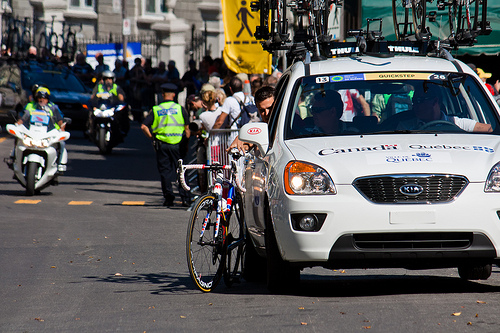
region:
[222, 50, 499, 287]
white car made by kia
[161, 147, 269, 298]
racing bicycle leaned against car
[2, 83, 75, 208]
man on a white motorcycle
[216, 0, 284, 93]
yellow sign with a black stick man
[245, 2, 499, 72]
bicycle rack on top of a white car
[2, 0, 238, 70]
grey stone building in the back ground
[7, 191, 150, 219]
yellow squares painted on the black road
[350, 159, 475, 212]
silver grill of the white car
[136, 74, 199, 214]
man wearing a yellow fluorescent vest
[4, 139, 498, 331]
black asphalt paved road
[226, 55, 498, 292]
a white car driving down a street.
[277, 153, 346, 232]
a right front headlight.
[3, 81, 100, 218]
a cop on a motorcycle.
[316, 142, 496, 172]
words painted on a hood.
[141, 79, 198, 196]
a neon green vest.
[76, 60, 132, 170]
a cop on a motorcycle.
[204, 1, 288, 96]
a banner with a man on it.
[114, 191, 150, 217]
the yellow stripe.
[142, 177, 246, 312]
the front tire of a bike.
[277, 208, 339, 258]
a right front light.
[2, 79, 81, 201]
a policeman riding a motorcycle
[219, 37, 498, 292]
car is white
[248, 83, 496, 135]
three persons in a car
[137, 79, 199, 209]
policeman with green vest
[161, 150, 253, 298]
bike lean on car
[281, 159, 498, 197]
headlights of car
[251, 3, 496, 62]
support to carry bikes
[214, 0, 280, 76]
yellow flag on a pole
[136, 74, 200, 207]
policeman wearing blue cap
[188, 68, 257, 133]
people behind a gate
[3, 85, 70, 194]
police officer riding a white and silver motorcycle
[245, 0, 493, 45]
the wheels of bicycles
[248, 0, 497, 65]
bicycles hitched to top of KIA white car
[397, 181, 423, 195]
the KIA logo on the front grill of white car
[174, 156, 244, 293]
white, blue and red bicycle against the white car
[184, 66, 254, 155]
a crowd of people behind the fence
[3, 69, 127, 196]
two motorcyclists driving motorcycles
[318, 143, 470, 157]
Canada Quebec written on hood of white car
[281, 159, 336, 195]
right head lights on the white car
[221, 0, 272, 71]
white sign with symbol of man walking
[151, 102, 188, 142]
the vest is green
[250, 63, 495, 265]
the make is kia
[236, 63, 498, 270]
the car is white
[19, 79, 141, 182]
the motorbikes are two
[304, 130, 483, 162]
the letters are canada que bee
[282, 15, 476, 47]
there are bikes on the roof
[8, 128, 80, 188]
the bike is white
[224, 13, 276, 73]
the sign is yellow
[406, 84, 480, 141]
the man has glasses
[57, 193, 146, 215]
the lines are yellow